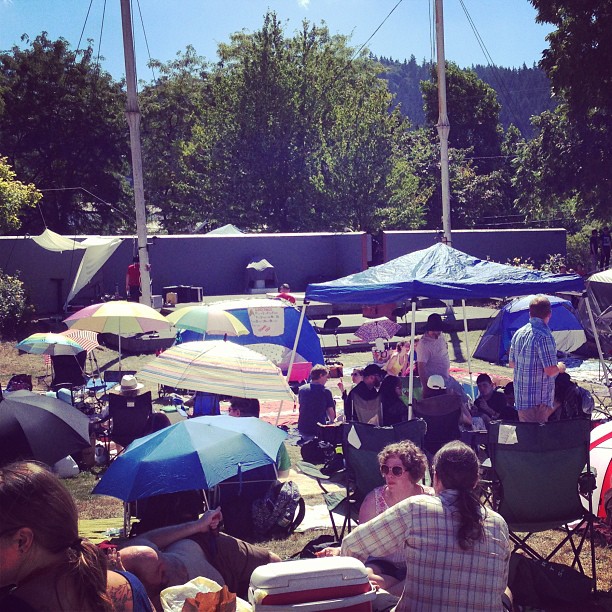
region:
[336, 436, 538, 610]
A man in a plaid shirt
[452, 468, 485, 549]
A ponytail on a man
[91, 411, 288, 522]
A blue umbrella in a park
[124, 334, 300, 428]
A striped umbrella in a park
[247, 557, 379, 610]
A cooler next to a man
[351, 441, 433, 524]
A woman in a pink blouse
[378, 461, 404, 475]
Black sunglasses on a woman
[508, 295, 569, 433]
A man in a plaid shirt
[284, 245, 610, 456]
A group of people sitting under a tent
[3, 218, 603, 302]
A blue fence at a park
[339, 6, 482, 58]
blue and clear sky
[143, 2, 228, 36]
no clouds in sky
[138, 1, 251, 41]
sky is bright blue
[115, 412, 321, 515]
blue umbrella in campsite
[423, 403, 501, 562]
person has long hair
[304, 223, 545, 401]
blue canopy over people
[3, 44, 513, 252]
tall and green trees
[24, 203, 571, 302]
grey wall behind people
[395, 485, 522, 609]
person has flannel shirt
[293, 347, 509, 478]
people sitting under blue canopy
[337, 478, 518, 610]
Man wearing a shirt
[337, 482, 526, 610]
Man is wearing a shirt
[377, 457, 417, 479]
Woman wearing sunglasses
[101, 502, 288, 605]
Man laying down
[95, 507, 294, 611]
Man is laying down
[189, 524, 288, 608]
Man is wearing brown shorts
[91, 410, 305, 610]
Man under a blue umbrella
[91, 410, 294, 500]
The blue umbrella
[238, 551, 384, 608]
The red and white cooler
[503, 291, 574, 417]
The man wearing a blue plaid shirt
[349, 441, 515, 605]
The person wearing a light colored tan shirt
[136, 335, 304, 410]
The striped umbrella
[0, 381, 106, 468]
The black umbrella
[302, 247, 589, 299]
The blue canopy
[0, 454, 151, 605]
The individual with a tattoo on her back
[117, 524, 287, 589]
The man with brown pants lying down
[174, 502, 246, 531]
hand holding umbrella handle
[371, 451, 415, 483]
sunglasses on woman's face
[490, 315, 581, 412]
man wearing blue plaid shirt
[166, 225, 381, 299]
purple wall in the rear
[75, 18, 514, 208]
lots of tall green trees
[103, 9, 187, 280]
tall silver masts with wires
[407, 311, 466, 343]
man wearing black hat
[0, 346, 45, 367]
green grass on the ground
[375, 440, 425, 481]
Hair on a woman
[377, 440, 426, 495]
Head of a woman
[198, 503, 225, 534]
Hand of a man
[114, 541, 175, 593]
Head of a man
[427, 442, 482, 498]
Head of a man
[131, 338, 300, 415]
Umbrella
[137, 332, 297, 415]
Colorful umbrella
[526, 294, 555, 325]
Head of a man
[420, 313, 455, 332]
Large hat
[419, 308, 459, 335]
Large black hat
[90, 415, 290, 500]
blue open umbrella being held by man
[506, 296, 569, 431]
man standing in a blue and white plaid shirt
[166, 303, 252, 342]
open pastel colored umbrella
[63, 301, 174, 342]
open pastel colored umbrella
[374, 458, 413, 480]
eyeglasses worn by woman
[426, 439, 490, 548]
man wears hair long